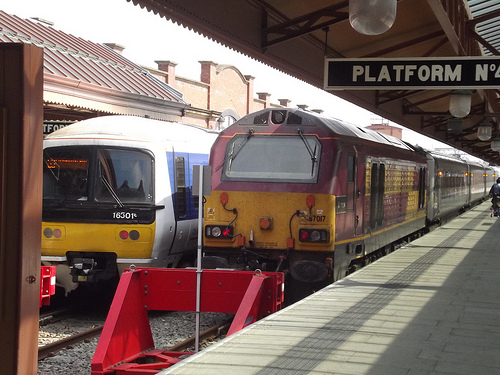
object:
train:
[196, 107, 499, 284]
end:
[200, 107, 337, 255]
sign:
[321, 56, 500, 90]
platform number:
[348, 64, 499, 82]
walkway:
[155, 198, 499, 374]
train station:
[0, 2, 498, 374]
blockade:
[91, 265, 287, 374]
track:
[33, 304, 233, 373]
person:
[485, 175, 498, 219]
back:
[492, 181, 500, 200]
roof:
[128, 1, 499, 165]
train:
[37, 113, 211, 305]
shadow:
[251, 206, 499, 374]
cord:
[287, 209, 301, 239]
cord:
[220, 204, 241, 227]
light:
[303, 194, 317, 212]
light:
[217, 192, 228, 209]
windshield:
[40, 148, 155, 217]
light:
[343, 2, 400, 38]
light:
[445, 91, 473, 122]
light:
[473, 125, 496, 143]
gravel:
[41, 338, 92, 368]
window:
[220, 135, 323, 186]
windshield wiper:
[211, 128, 254, 176]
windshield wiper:
[286, 124, 320, 160]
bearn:
[0, 41, 45, 374]